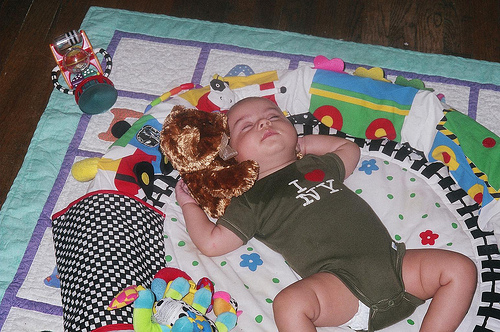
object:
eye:
[240, 124, 254, 134]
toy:
[103, 266, 238, 332]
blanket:
[0, 5, 500, 332]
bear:
[158, 104, 259, 220]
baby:
[174, 96, 477, 332]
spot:
[245, 161, 308, 204]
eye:
[268, 115, 281, 120]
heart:
[304, 169, 326, 183]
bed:
[51, 54, 499, 332]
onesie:
[215, 152, 424, 332]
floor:
[120, 0, 500, 56]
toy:
[50, 28, 118, 115]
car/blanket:
[114, 148, 156, 197]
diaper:
[336, 300, 371, 331]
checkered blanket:
[50, 189, 166, 332]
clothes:
[215, 153, 425, 332]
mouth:
[260, 130, 280, 141]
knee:
[436, 251, 478, 295]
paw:
[227, 159, 261, 198]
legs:
[273, 248, 477, 332]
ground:
[0, 0, 500, 332]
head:
[225, 96, 299, 172]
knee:
[272, 291, 300, 314]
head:
[159, 104, 231, 173]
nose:
[257, 119, 272, 131]